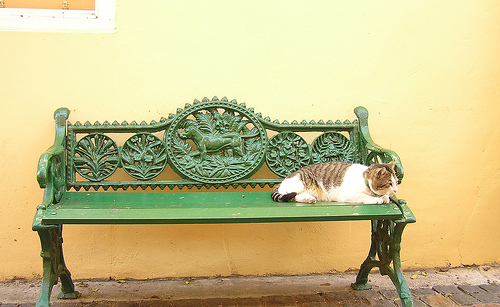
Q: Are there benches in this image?
A: Yes, there is a bench.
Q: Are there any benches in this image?
A: Yes, there is a bench.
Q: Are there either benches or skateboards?
A: Yes, there is a bench.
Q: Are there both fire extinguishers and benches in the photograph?
A: No, there is a bench but no fire extinguishers.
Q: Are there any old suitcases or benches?
A: Yes, there is an old bench.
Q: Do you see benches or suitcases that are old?
A: Yes, the bench is old.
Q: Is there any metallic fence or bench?
A: Yes, there is a metal bench.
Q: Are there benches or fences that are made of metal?
A: Yes, the bench is made of metal.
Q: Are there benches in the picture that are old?
A: Yes, there is an old bench.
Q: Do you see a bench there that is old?
A: Yes, there is a bench that is old.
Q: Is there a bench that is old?
A: Yes, there is a bench that is old.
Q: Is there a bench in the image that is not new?
A: Yes, there is a old bench.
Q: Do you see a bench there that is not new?
A: Yes, there is a old bench.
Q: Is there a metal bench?
A: Yes, there is a bench that is made of metal.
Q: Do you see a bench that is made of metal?
A: Yes, there is a bench that is made of metal.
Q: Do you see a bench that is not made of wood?
A: Yes, there is a bench that is made of metal.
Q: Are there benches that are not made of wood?
A: Yes, there is a bench that is made of metal.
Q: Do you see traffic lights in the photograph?
A: No, there are no traffic lights.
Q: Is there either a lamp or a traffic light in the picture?
A: No, there are no traffic lights or lamps.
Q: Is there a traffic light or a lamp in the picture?
A: No, there are no traffic lights or lamps.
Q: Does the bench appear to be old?
A: Yes, the bench is old.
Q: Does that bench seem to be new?
A: No, the bench is old.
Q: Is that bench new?
A: No, the bench is old.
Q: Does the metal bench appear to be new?
A: No, the bench is old.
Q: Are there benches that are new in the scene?
A: No, there is a bench but it is old.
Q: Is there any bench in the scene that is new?
A: No, there is a bench but it is old.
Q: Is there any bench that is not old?
A: No, there is a bench but it is old.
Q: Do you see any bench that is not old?
A: No, there is a bench but it is old.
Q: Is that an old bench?
A: Yes, that is an old bench.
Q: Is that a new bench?
A: No, that is an old bench.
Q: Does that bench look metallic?
A: Yes, the bench is metallic.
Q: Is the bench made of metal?
A: Yes, the bench is made of metal.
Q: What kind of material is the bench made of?
A: The bench is made of metal.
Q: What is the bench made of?
A: The bench is made of metal.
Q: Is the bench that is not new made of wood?
A: No, the bench is made of metal.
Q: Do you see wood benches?
A: No, there is a bench but it is made of metal.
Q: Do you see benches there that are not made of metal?
A: No, there is a bench but it is made of metal.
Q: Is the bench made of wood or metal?
A: The bench is made of metal.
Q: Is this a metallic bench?
A: Yes, this is a metallic bench.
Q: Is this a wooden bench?
A: No, this is a metallic bench.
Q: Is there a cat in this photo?
A: Yes, there is a cat.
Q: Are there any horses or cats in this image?
A: Yes, there is a cat.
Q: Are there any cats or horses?
A: Yes, there is a cat.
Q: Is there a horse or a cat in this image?
A: Yes, there is a cat.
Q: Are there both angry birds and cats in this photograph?
A: No, there is a cat but no angry birds.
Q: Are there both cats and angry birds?
A: No, there is a cat but no angry birds.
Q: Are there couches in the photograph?
A: No, there are no couches.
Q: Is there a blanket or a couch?
A: No, there are no couches or blankets.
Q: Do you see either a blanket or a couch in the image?
A: No, there are no couches or blankets.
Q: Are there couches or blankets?
A: No, there are no couches or blankets.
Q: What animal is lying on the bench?
A: The cat is lying on the bench.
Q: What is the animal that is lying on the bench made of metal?
A: The animal is a cat.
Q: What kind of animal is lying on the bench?
A: The animal is a cat.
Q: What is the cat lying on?
A: The cat is lying on the bench.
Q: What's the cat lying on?
A: The cat is lying on the bench.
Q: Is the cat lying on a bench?
A: Yes, the cat is lying on a bench.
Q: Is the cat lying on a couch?
A: No, the cat is lying on a bench.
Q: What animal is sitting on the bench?
A: The cat is sitting on the bench.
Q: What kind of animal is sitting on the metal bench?
A: The animal is a cat.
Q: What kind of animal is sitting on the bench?
A: The animal is a cat.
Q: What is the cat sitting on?
A: The cat is sitting on the bench.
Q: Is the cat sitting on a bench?
A: Yes, the cat is sitting on a bench.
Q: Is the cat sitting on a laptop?
A: No, the cat is sitting on a bench.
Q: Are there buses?
A: No, there are no buses.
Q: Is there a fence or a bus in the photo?
A: No, there are no buses or fences.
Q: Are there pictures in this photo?
A: No, there are no pictures.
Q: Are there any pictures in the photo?
A: No, there are no pictures.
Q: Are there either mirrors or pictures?
A: No, there are no pictures or mirrors.